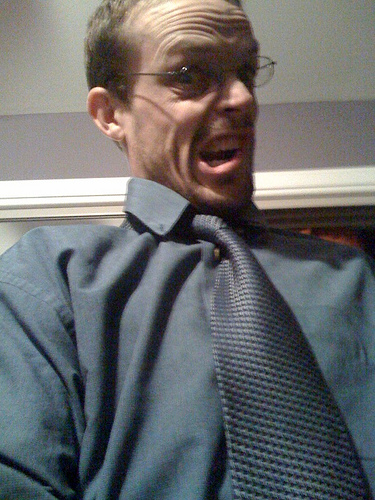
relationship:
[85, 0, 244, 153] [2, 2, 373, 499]
hair on man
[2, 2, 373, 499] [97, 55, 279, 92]
man wears glasses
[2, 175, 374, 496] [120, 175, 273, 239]
shirt has collar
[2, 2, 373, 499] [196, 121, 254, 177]
man has mouth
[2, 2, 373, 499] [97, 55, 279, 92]
man wearing glasses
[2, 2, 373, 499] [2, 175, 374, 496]
man wearing shirt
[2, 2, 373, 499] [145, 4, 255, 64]
man has wrinkles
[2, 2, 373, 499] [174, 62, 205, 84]
man has eye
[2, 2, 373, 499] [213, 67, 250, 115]
man has nose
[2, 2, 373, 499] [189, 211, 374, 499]
man wearing tie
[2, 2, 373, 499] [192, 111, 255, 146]
man has facial hair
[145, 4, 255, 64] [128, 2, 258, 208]
wrinkles on face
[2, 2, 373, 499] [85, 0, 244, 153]
man has hair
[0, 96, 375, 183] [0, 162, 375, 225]
wall above trim